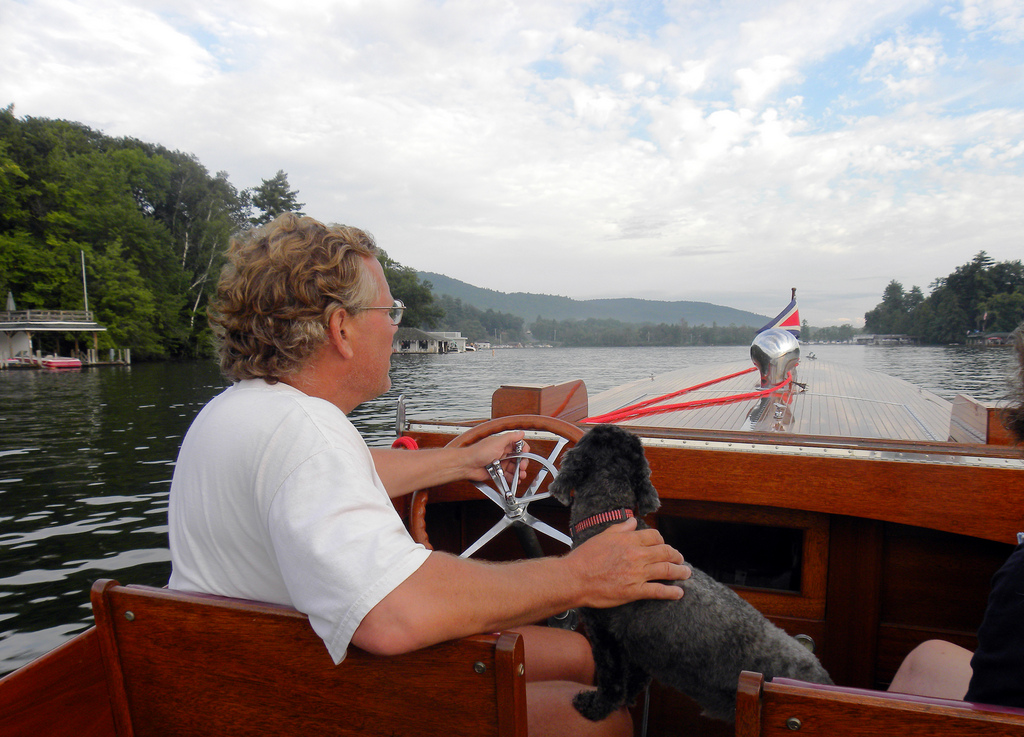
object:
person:
[167, 213, 690, 737]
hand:
[564, 517, 692, 608]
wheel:
[411, 415, 587, 558]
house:
[0, 251, 131, 367]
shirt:
[169, 376, 434, 664]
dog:
[548, 423, 836, 722]